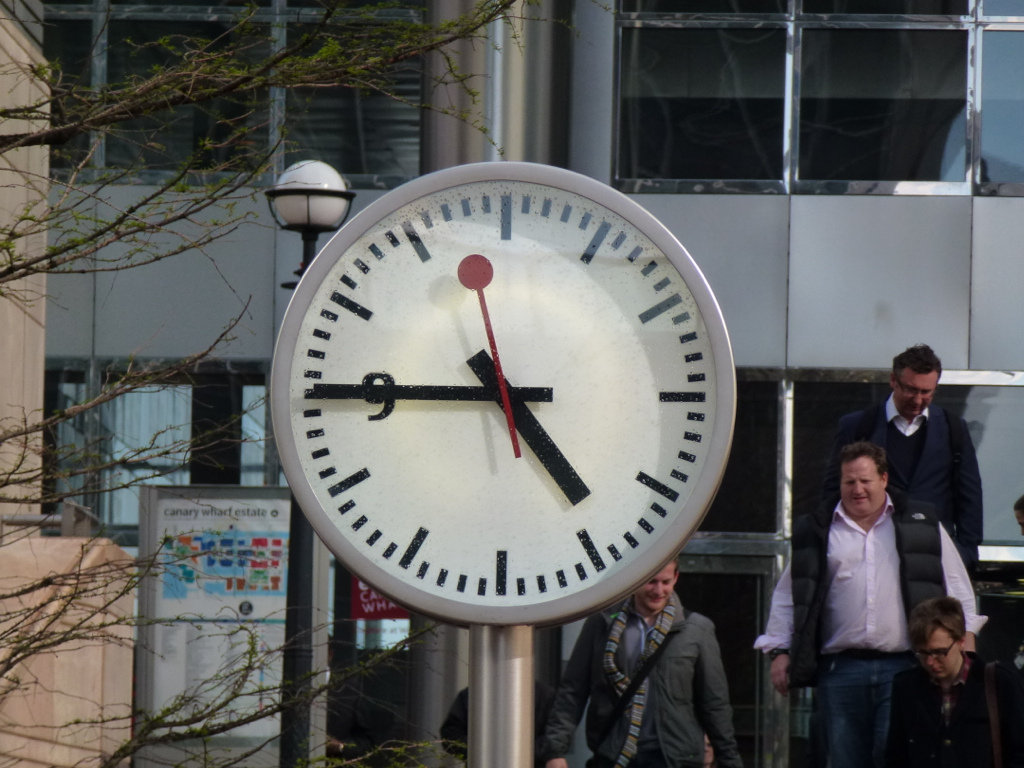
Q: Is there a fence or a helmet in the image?
A: No, there are no helmets or fences.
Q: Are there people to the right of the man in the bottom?
A: Yes, there is a person to the right of the man.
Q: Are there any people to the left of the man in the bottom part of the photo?
A: No, the person is to the right of the man.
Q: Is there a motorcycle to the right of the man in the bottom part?
A: No, there is a person to the right of the man.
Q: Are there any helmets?
A: No, there are no helmets.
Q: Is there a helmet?
A: No, there are no helmets.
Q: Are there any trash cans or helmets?
A: No, there are no helmets or trash cans.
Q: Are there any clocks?
A: Yes, there is a clock.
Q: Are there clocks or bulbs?
A: Yes, there is a clock.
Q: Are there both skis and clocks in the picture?
A: No, there is a clock but no skis.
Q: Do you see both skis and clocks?
A: No, there is a clock but no skis.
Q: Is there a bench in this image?
A: No, there are no benches.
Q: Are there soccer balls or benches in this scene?
A: No, there are no benches or soccer balls.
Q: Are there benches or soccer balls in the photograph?
A: No, there are no benches or soccer balls.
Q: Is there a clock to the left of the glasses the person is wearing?
A: Yes, there is a clock to the left of the glasses.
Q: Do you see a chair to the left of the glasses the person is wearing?
A: No, there is a clock to the left of the glasses.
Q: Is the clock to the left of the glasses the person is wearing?
A: Yes, the clock is to the left of the glasses.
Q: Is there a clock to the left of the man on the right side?
A: Yes, there is a clock to the left of the man.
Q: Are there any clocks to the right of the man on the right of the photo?
A: No, the clock is to the left of the man.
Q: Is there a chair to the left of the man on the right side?
A: No, there is a clock to the left of the man.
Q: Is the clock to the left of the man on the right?
A: Yes, the clock is to the left of the man.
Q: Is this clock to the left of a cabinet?
A: No, the clock is to the left of the man.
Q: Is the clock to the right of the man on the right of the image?
A: No, the clock is to the left of the man.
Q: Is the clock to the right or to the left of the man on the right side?
A: The clock is to the left of the man.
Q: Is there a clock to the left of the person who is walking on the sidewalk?
A: Yes, there is a clock to the left of the person.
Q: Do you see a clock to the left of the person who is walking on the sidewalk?
A: Yes, there is a clock to the left of the person.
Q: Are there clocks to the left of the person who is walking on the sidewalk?
A: Yes, there is a clock to the left of the person.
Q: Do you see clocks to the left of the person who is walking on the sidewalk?
A: Yes, there is a clock to the left of the person.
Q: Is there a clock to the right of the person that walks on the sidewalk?
A: No, the clock is to the left of the person.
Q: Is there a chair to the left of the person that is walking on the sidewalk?
A: No, there is a clock to the left of the person.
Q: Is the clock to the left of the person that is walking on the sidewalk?
A: Yes, the clock is to the left of the person.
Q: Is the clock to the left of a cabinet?
A: No, the clock is to the left of the person.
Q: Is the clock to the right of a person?
A: No, the clock is to the left of a person.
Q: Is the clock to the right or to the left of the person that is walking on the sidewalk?
A: The clock is to the left of the person.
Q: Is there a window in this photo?
A: Yes, there is a window.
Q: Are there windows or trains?
A: Yes, there is a window.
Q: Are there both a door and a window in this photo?
A: No, there is a window but no doors.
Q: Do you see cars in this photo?
A: No, there are no cars.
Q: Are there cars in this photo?
A: No, there are no cars.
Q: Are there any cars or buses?
A: No, there are no cars or buses.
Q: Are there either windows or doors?
A: Yes, there is a window.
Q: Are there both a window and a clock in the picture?
A: Yes, there are both a window and a clock.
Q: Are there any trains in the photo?
A: No, there are no trains.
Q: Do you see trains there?
A: No, there are no trains.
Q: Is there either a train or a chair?
A: No, there are no trains or chairs.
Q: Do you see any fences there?
A: No, there are no fences.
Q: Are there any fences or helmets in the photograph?
A: No, there are no fences or helmets.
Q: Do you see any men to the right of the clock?
A: Yes, there is a man to the right of the clock.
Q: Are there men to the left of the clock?
A: No, the man is to the right of the clock.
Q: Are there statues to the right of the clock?
A: No, there is a man to the right of the clock.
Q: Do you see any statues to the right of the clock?
A: No, there is a man to the right of the clock.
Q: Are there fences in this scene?
A: No, there are no fences.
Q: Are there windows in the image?
A: Yes, there is a window.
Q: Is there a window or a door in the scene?
A: Yes, there is a window.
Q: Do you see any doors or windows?
A: Yes, there is a window.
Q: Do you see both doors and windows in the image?
A: No, there is a window but no doors.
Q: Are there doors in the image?
A: No, there are no doors.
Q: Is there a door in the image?
A: No, there are no doors.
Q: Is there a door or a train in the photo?
A: No, there are no doors or trains.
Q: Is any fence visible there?
A: No, there are no fences.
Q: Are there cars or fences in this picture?
A: No, there are no fences or cars.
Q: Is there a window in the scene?
A: Yes, there is a window.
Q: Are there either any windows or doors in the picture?
A: Yes, there is a window.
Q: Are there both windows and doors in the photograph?
A: No, there is a window but no doors.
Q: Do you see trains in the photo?
A: No, there are no trains.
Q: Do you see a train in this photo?
A: No, there are no trains.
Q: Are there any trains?
A: No, there are no trains.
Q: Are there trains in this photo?
A: No, there are no trains.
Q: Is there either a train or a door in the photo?
A: No, there are no trains or doors.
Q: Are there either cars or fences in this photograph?
A: No, there are no fences or cars.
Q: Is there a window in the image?
A: Yes, there is a window.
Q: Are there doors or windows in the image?
A: Yes, there is a window.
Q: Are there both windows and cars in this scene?
A: No, there is a window but no cars.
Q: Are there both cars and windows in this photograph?
A: No, there is a window but no cars.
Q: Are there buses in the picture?
A: No, there are no buses.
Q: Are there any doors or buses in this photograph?
A: No, there are no buses or doors.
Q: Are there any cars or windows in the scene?
A: Yes, there is a window.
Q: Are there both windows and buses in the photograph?
A: No, there is a window but no buses.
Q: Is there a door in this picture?
A: No, there are no doors.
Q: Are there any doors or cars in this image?
A: No, there are no doors or cars.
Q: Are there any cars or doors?
A: No, there are no doors or cars.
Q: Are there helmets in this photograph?
A: No, there are no helmets.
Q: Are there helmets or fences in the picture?
A: No, there are no helmets or fences.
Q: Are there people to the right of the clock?
A: Yes, there is a person to the right of the clock.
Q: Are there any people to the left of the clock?
A: No, the person is to the right of the clock.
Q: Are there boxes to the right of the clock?
A: No, there is a person to the right of the clock.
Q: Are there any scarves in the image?
A: Yes, there is a scarf.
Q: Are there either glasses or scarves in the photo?
A: Yes, there is a scarf.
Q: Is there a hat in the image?
A: No, there are no hats.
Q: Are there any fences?
A: No, there are no fences.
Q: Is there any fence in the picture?
A: No, there are no fences.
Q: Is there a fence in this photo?
A: No, there are no fences.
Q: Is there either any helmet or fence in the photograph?
A: No, there are no fences or helmets.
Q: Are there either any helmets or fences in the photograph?
A: No, there are no fences or helmets.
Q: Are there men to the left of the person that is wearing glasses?
A: Yes, there is a man to the left of the person.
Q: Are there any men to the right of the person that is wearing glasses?
A: No, the man is to the left of the person.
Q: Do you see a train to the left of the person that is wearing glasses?
A: No, there is a man to the left of the person.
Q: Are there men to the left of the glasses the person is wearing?
A: Yes, there is a man to the left of the glasses.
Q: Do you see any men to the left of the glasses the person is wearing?
A: Yes, there is a man to the left of the glasses.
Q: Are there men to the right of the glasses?
A: No, the man is to the left of the glasses.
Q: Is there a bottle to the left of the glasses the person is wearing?
A: No, there is a man to the left of the glasses.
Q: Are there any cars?
A: No, there are no cars.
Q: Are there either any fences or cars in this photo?
A: No, there are no cars or fences.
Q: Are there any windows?
A: Yes, there is a window.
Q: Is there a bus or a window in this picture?
A: Yes, there is a window.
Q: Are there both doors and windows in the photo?
A: No, there is a window but no doors.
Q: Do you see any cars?
A: No, there are no cars.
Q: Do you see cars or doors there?
A: No, there are no cars or doors.